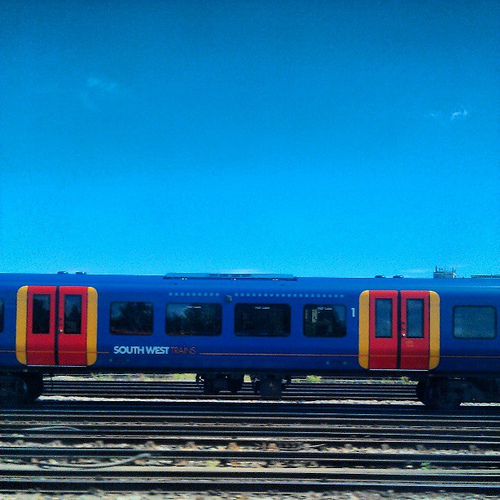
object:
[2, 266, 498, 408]
train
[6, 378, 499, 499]
tracks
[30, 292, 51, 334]
windows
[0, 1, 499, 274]
sky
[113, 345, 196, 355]
writing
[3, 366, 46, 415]
wheels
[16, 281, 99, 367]
doors